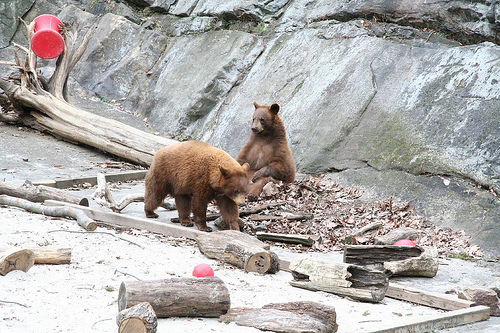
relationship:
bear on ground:
[143, 140, 250, 232] [1, 118, 500, 332]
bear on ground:
[238, 103, 295, 199] [1, 118, 500, 332]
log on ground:
[0, 16, 184, 169] [1, 118, 500, 332]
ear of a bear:
[220, 167, 231, 177] [143, 140, 250, 232]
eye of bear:
[260, 117, 265, 121] [238, 103, 295, 199]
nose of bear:
[251, 125, 259, 132] [238, 103, 295, 199]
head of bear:
[220, 163, 253, 207] [143, 140, 250, 232]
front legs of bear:
[194, 194, 241, 233] [143, 140, 250, 232]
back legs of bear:
[146, 175, 194, 227] [143, 140, 250, 232]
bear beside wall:
[143, 140, 250, 232] [1, 1, 498, 257]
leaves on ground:
[251, 176, 477, 260] [1, 118, 500, 332]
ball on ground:
[192, 263, 215, 277] [1, 118, 500, 332]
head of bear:
[252, 102, 286, 135] [238, 103, 295, 199]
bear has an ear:
[143, 140, 250, 232] [220, 167, 231, 177]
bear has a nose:
[238, 103, 295, 199] [251, 125, 259, 132]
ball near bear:
[192, 263, 215, 277] [143, 140, 250, 232]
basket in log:
[31, 15, 67, 60] [0, 16, 184, 169]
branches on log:
[1, 15, 103, 122] [0, 16, 184, 169]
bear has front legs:
[143, 140, 250, 232] [194, 194, 241, 233]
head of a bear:
[220, 163, 253, 207] [143, 140, 250, 232]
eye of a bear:
[260, 117, 265, 121] [238, 103, 295, 199]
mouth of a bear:
[253, 128, 269, 133] [238, 103, 295, 199]